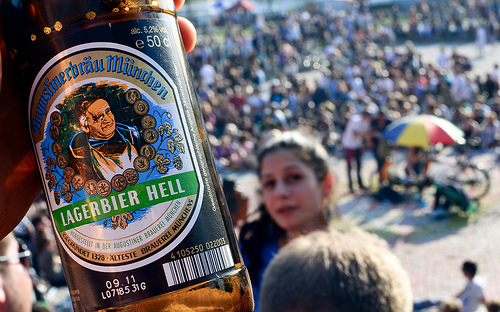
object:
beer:
[73, 54, 188, 267]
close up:
[50, 89, 131, 312]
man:
[341, 110, 374, 194]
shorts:
[342, 146, 366, 166]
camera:
[0, 2, 500, 312]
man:
[1, 230, 36, 312]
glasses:
[0, 238, 33, 270]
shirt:
[238, 234, 279, 308]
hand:
[3, 0, 197, 243]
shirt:
[341, 113, 370, 148]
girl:
[239, 131, 415, 312]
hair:
[238, 137, 327, 284]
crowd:
[178, 1, 500, 311]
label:
[23, 15, 241, 311]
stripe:
[50, 170, 199, 233]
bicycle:
[369, 158, 489, 199]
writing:
[32, 54, 168, 134]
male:
[68, 96, 141, 182]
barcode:
[162, 243, 235, 287]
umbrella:
[380, 115, 466, 151]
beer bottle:
[0, 0, 258, 311]